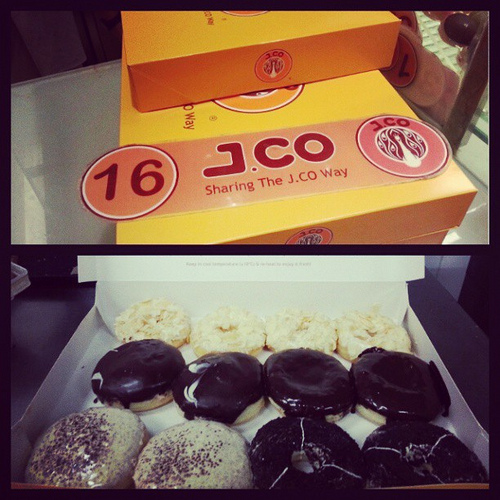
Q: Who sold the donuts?
A: J. CO.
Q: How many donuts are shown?
A: Twelve.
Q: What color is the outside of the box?
A: Orange.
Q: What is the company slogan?
A: Sharing The J. CO Way.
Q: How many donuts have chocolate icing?
A: Four.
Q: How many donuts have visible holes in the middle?
A: Six.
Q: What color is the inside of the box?
A: White.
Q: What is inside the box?
A: Donuts.